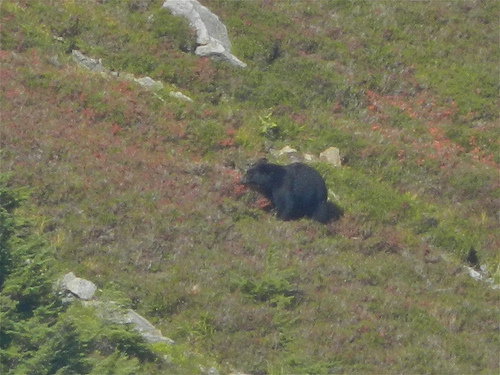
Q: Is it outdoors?
A: Yes, it is outdoors.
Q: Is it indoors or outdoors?
A: It is outdoors.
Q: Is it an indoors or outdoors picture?
A: It is outdoors.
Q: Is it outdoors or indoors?
A: It is outdoors.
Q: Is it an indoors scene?
A: No, it is outdoors.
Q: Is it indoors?
A: No, it is outdoors.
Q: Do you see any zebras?
A: No, there are no zebras.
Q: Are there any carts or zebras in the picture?
A: No, there are no zebras or carts.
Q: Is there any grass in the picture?
A: Yes, there is grass.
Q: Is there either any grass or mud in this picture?
A: Yes, there is grass.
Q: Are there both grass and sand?
A: No, there is grass but no sand.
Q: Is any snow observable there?
A: No, there is no snow.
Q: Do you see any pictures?
A: No, there are no pictures.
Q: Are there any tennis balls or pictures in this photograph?
A: No, there are no pictures or tennis balls.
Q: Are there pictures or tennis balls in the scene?
A: No, there are no pictures or tennis balls.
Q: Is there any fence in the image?
A: No, there are no fences.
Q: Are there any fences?
A: No, there are no fences.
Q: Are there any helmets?
A: No, there are no helmets.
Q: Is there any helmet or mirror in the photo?
A: No, there are no helmets or mirrors.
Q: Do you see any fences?
A: No, there are no fences.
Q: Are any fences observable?
A: No, there are no fences.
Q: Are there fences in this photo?
A: No, there are no fences.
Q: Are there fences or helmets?
A: No, there are no fences or helmets.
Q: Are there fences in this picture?
A: No, there are no fences.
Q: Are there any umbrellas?
A: No, there are no umbrellas.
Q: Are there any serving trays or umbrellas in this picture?
A: No, there are no umbrellas or serving trays.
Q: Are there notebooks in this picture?
A: No, there are no notebooks.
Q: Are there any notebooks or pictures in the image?
A: No, there are no notebooks or pictures.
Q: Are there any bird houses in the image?
A: No, there are no bird houses.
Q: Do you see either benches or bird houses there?
A: No, there are no bird houses or benches.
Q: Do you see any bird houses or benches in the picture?
A: No, there are no bird houses or benches.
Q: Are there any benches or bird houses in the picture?
A: No, there are no bird houses or benches.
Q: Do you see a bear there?
A: Yes, there is a bear.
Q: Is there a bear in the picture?
A: Yes, there is a bear.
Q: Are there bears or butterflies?
A: Yes, there is a bear.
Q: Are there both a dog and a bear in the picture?
A: No, there is a bear but no dogs.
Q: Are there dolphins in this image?
A: No, there are no dolphins.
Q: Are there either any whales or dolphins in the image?
A: No, there are no dolphins or whales.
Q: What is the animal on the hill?
A: The animal is a bear.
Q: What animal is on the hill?
A: The animal is a bear.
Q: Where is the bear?
A: The bear is on the hill.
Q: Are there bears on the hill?
A: Yes, there is a bear on the hill.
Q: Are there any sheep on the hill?
A: No, there is a bear on the hill.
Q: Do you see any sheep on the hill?
A: No, there is a bear on the hill.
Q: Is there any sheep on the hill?
A: No, there is a bear on the hill.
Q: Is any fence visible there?
A: No, there are no fences.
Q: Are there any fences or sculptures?
A: No, there are no fences or sculptures.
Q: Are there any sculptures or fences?
A: No, there are no fences or sculptures.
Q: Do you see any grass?
A: Yes, there is grass.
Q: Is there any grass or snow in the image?
A: Yes, there is grass.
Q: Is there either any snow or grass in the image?
A: Yes, there is grass.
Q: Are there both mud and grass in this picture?
A: No, there is grass but no mud.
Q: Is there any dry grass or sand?
A: Yes, there is dry grass.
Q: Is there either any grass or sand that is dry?
A: Yes, the grass is dry.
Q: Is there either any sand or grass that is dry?
A: Yes, the grass is dry.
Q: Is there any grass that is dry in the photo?
A: Yes, there is dry grass.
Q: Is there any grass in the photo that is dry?
A: Yes, there is grass that is dry.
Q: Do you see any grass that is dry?
A: Yes, there is grass that is dry.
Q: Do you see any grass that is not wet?
A: Yes, there is dry grass.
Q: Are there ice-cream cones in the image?
A: No, there are no ice-cream cones.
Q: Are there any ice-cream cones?
A: No, there are no ice-cream cones.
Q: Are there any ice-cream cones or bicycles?
A: No, there are no ice-cream cones or bicycles.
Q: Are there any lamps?
A: No, there are no lamps.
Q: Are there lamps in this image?
A: No, there are no lamps.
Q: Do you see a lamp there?
A: No, there are no lamps.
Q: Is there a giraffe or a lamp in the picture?
A: No, there are no lamps or giraffes.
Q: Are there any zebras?
A: No, there are no zebras.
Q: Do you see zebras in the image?
A: No, there are no zebras.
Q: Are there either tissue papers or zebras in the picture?
A: No, there are no zebras or tissue papers.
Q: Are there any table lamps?
A: No, there are no table lamps.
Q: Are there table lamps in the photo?
A: No, there are no table lamps.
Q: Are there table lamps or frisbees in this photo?
A: No, there are no table lamps or frisbees.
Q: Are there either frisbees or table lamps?
A: No, there are no table lamps or frisbees.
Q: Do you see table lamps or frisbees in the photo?
A: No, there are no table lamps or frisbees.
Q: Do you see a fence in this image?
A: No, there are no fences.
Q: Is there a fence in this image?
A: No, there are no fences.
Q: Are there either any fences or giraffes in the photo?
A: No, there are no fences or giraffes.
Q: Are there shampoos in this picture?
A: No, there are no shampoos.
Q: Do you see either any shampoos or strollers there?
A: No, there are no shampoos or strollers.